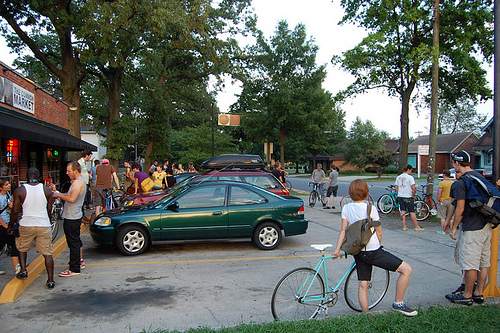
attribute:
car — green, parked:
[99, 185, 310, 256]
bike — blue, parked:
[257, 214, 410, 332]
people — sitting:
[38, 139, 150, 280]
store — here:
[0, 31, 125, 235]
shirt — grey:
[66, 184, 100, 231]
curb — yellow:
[6, 212, 75, 301]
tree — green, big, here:
[364, 22, 439, 158]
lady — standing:
[0, 172, 23, 283]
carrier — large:
[200, 152, 261, 174]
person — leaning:
[347, 169, 418, 321]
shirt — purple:
[134, 169, 151, 188]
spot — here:
[67, 232, 341, 266]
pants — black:
[60, 212, 97, 279]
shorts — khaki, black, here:
[13, 221, 74, 262]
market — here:
[5, 69, 96, 207]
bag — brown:
[337, 213, 383, 246]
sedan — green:
[96, 181, 318, 251]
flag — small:
[211, 112, 260, 142]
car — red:
[178, 170, 312, 209]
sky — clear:
[275, 14, 361, 97]